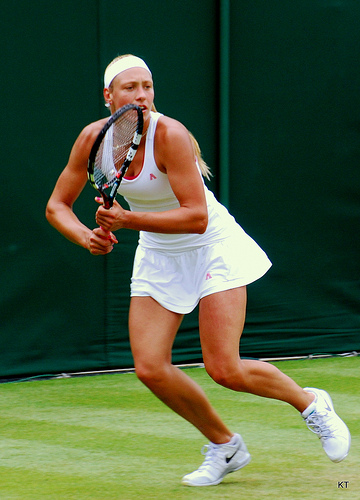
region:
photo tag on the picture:
[334, 473, 350, 491]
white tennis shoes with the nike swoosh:
[169, 393, 357, 482]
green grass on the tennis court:
[14, 386, 134, 486]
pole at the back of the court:
[206, 0, 242, 183]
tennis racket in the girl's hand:
[82, 99, 147, 261]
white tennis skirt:
[123, 230, 283, 312]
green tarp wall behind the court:
[249, 72, 328, 277]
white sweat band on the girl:
[97, 53, 157, 85]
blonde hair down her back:
[187, 129, 219, 185]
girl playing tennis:
[28, 53, 305, 403]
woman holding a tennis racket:
[49, 70, 233, 305]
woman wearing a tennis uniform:
[72, 87, 334, 368]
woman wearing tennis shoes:
[161, 391, 358, 495]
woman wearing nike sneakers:
[163, 366, 357, 497]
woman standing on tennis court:
[22, 19, 357, 498]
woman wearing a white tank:
[85, 105, 244, 243]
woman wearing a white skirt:
[120, 215, 289, 325]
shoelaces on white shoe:
[303, 410, 340, 442]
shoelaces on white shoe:
[199, 443, 224, 477]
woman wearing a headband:
[98, 50, 159, 88]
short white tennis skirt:
[133, 246, 270, 300]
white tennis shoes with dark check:
[307, 389, 350, 458]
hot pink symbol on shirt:
[148, 173, 158, 181]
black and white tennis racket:
[87, 106, 142, 201]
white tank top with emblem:
[143, 125, 172, 214]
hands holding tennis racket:
[92, 191, 119, 257]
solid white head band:
[100, 57, 151, 80]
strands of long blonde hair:
[197, 140, 209, 180]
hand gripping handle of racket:
[97, 205, 128, 231]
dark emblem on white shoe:
[221, 448, 243, 462]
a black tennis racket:
[62, 90, 158, 235]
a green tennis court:
[25, 391, 156, 478]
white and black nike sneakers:
[179, 376, 358, 498]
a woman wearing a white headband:
[71, 43, 182, 128]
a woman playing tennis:
[42, 42, 251, 253]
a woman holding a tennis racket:
[40, 41, 191, 215]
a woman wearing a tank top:
[46, 56, 203, 226]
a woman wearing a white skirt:
[78, 73, 266, 322]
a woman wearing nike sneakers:
[66, 51, 344, 495]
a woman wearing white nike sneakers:
[71, 50, 359, 479]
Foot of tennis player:
[181, 432, 255, 485]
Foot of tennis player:
[298, 386, 353, 468]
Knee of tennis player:
[134, 359, 166, 383]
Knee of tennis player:
[206, 359, 243, 383]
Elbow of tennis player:
[177, 206, 211, 237]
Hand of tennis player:
[81, 226, 120, 257]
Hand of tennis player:
[92, 194, 128, 234]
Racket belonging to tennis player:
[80, 103, 146, 206]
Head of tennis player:
[98, 53, 159, 125]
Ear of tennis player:
[99, 89, 113, 101]